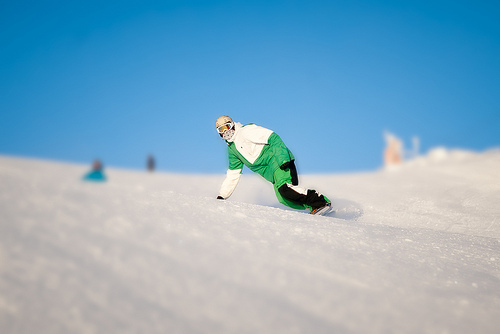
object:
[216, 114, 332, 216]
person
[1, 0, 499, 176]
sky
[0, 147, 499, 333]
snow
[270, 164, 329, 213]
pants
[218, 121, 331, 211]
snow suit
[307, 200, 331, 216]
snowboard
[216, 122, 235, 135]
ski goggles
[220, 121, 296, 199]
ski jacket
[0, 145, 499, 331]
mountain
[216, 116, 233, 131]
helmet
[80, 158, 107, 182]
person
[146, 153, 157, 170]
figure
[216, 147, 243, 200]
arm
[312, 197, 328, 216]
boot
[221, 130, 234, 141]
bandana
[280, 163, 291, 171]
glove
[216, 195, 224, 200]
glove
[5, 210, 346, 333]
tracks